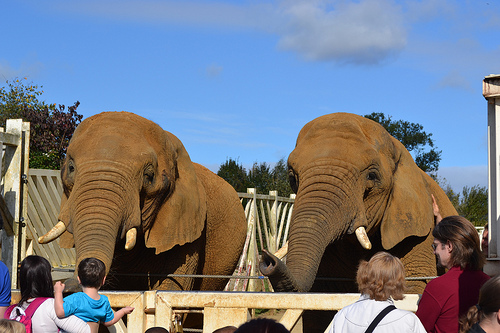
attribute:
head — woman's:
[10, 242, 45, 292]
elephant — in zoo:
[35, 81, 217, 308]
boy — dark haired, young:
[54, 258, 135, 330]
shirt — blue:
[63, 293, 114, 320]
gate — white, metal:
[23, 277, 314, 329]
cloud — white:
[259, 4, 439, 97]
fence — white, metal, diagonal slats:
[208, 180, 310, 297]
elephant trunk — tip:
[240, 197, 342, 311]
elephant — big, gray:
[306, 111, 401, 218]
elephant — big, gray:
[71, 110, 195, 247]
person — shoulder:
[320, 249, 433, 331]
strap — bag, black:
[360, 302, 394, 331]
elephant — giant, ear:
[39, 107, 249, 296]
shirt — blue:
[65, 287, 120, 317]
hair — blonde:
[362, 259, 397, 294]